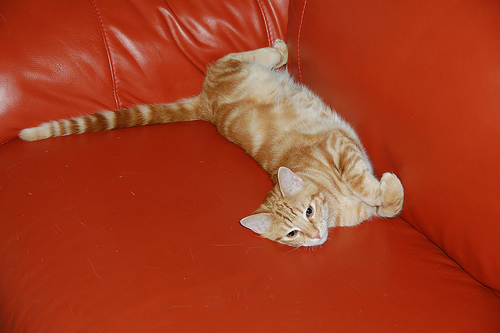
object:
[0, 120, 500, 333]
cushion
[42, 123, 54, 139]
stripe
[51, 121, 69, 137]
stripe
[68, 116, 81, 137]
stripe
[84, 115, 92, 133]
stripe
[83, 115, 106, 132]
stripe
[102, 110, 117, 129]
stripe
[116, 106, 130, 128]
stripe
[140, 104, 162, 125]
stripe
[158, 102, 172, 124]
stripe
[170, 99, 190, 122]
stripe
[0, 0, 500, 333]
couch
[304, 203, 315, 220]
eye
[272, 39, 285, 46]
feet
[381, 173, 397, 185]
paws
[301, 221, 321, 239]
nose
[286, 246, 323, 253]
whiskers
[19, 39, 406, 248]
cat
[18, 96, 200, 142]
tail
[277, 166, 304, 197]
ear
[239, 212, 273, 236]
ear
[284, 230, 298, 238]
eye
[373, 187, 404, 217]
legs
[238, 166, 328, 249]
head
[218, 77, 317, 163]
fur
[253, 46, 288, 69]
legs